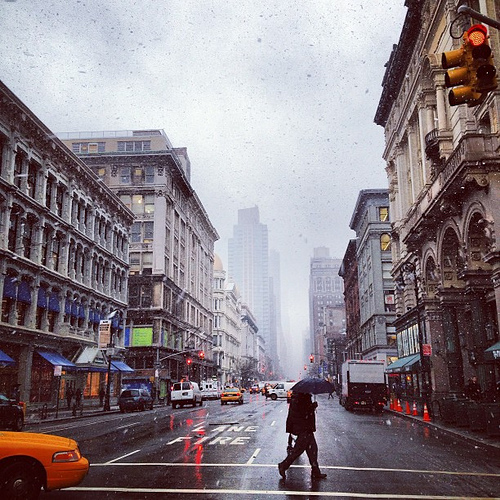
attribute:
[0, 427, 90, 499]
taxi — yellow, driving, turning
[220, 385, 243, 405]
taxi — yellow, driving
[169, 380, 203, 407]
van — white, driving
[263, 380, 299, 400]
van — white, driving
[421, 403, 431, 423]
cone — orange, reflective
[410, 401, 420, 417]
cone — orange, reflective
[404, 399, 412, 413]
cone — orange, reflective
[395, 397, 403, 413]
cone — orange, reflective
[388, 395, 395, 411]
cone — orange, reflective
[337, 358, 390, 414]
box truck — white, parked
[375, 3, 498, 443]
building — tall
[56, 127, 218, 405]
building — tall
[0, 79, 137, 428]
building — tall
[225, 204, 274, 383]
building — tall, large, skyscraper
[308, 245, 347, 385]
building — tall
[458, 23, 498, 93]
stoplight — red, hanging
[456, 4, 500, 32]
pole — metal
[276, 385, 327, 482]
person — walking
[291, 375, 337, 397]
umbrella — blue, black